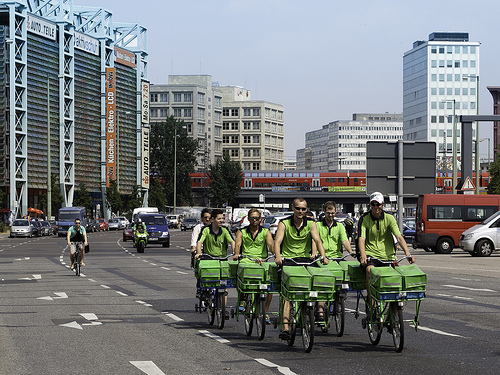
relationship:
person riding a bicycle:
[65, 215, 94, 245] [63, 247, 91, 274]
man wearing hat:
[355, 191, 426, 274] [367, 193, 391, 210]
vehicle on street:
[8, 217, 36, 241] [4, 227, 499, 361]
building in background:
[218, 85, 291, 180] [60, 2, 499, 164]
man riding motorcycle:
[132, 217, 153, 237] [132, 230, 153, 256]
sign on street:
[138, 126, 155, 197] [4, 227, 499, 361]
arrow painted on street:
[58, 310, 104, 336] [4, 227, 499, 361]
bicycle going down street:
[272, 255, 337, 353] [4, 227, 499, 361]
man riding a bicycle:
[355, 191, 426, 274] [362, 288, 416, 357]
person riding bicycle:
[65, 215, 94, 245] [63, 247, 91, 274]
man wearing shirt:
[355, 191, 426, 274] [357, 216, 406, 268]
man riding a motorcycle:
[132, 217, 153, 237] [132, 230, 153, 256]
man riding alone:
[67, 217, 91, 279] [56, 217, 108, 280]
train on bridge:
[185, 168, 370, 192] [188, 184, 369, 203]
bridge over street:
[188, 184, 369, 203] [4, 227, 499, 361]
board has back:
[357, 137, 448, 208] [378, 150, 403, 197]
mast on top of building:
[224, 80, 258, 103] [218, 85, 291, 180]